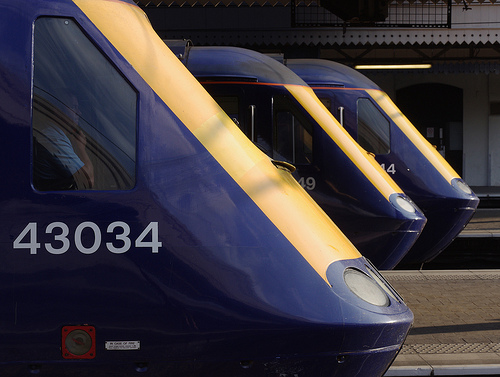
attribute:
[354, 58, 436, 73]
light — off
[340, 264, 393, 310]
head light — off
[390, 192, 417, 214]
head light — off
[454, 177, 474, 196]
head light — off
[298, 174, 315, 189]
numbers — white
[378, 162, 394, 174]
numbers — white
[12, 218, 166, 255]
numbers — white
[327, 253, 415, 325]
headlight — off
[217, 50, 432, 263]
front — yellow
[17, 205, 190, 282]
numbers — white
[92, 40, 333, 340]
train — still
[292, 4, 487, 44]
grate — metal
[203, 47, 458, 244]
trains — passenger trains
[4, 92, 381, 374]
trains — stopped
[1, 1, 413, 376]
train — blue , yellow, still, parked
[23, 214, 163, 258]
number — 43034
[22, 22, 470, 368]
trains — same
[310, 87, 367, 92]
stripe — red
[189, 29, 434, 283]
train — parked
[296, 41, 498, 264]
train — parked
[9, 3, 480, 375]
trains — stopped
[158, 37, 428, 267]
train — still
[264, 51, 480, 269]
train — still